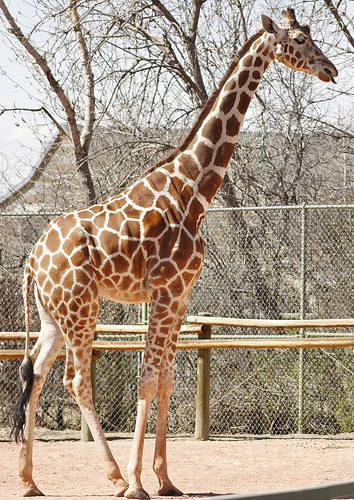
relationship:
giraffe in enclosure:
[7, 3, 338, 499] [1, 200, 354, 499]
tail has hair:
[6, 267, 41, 449] [5, 356, 40, 447]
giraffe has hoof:
[7, 3, 338, 499] [154, 480, 190, 499]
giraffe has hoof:
[7, 3, 338, 499] [119, 483, 153, 499]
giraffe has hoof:
[7, 3, 338, 499] [106, 474, 134, 499]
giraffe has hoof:
[7, 3, 338, 499] [18, 478, 49, 499]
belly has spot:
[96, 273, 153, 310] [113, 271, 140, 294]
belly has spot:
[96, 273, 153, 310] [125, 279, 144, 296]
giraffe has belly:
[7, 3, 338, 499] [96, 273, 153, 310]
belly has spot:
[96, 273, 153, 310] [100, 277, 119, 293]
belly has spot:
[96, 273, 153, 310] [118, 289, 134, 304]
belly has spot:
[96, 273, 153, 310] [98, 258, 117, 280]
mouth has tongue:
[316, 59, 341, 89] [326, 69, 342, 88]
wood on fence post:
[1, 310, 354, 363] [191, 307, 221, 443]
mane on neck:
[137, 18, 299, 197] [154, 22, 282, 230]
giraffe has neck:
[7, 3, 338, 499] [154, 22, 282, 230]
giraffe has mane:
[7, 3, 338, 499] [137, 18, 299, 197]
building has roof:
[5, 117, 353, 430] [3, 117, 352, 210]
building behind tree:
[5, 117, 353, 430] [1, 2, 138, 431]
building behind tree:
[5, 117, 353, 430] [97, 2, 292, 351]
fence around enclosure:
[1, 200, 354, 444] [1, 200, 354, 499]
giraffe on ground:
[7, 3, 338, 499] [2, 431, 353, 500]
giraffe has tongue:
[7, 3, 338, 499] [326, 69, 342, 88]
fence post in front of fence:
[191, 307, 221, 443] [1, 200, 354, 444]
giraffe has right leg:
[7, 3, 338, 499] [66, 369, 132, 500]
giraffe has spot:
[7, 3, 338, 499] [125, 279, 144, 296]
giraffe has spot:
[7, 3, 338, 499] [118, 289, 134, 304]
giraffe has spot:
[7, 3, 338, 499] [113, 271, 140, 294]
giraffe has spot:
[7, 3, 338, 499] [100, 277, 119, 293]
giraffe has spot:
[7, 3, 338, 499] [98, 258, 117, 280]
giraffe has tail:
[7, 3, 338, 499] [6, 267, 41, 449]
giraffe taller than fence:
[7, 3, 338, 499] [1, 200, 354, 444]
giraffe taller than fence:
[7, 3, 338, 499] [1, 311, 353, 440]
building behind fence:
[5, 117, 353, 430] [1, 200, 354, 444]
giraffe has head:
[7, 3, 338, 499] [258, 4, 343, 90]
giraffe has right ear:
[7, 3, 338, 499] [257, 12, 280, 37]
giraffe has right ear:
[7, 3, 338, 499] [255, 10, 287, 40]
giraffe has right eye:
[7, 3, 338, 499] [290, 31, 309, 50]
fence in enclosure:
[1, 309, 353, 445] [1, 200, 354, 499]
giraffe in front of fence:
[7, 3, 338, 499] [1, 200, 354, 444]